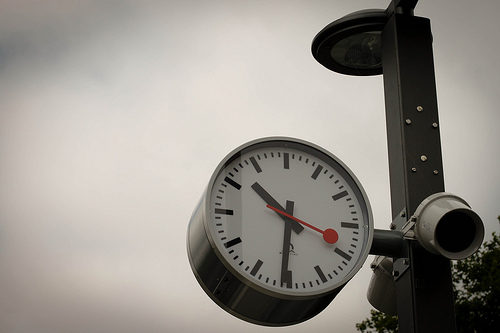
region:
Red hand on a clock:
[263, 198, 348, 246]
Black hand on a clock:
[245, 179, 305, 291]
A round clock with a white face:
[171, 136, 380, 332]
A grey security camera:
[398, 182, 498, 262]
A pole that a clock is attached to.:
[308, 7, 490, 332]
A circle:
[194, 130, 376, 312]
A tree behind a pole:
[329, 206, 498, 332]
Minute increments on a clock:
[253, 148, 288, 165]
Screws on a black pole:
[386, 91, 446, 188]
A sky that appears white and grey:
[3, 7, 185, 274]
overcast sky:
[14, 8, 174, 315]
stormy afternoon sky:
[7, 11, 176, 320]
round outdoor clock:
[182, 125, 384, 332]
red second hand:
[252, 202, 346, 247]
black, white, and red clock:
[166, 137, 388, 332]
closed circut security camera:
[389, 182, 494, 276]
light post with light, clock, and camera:
[118, 5, 495, 329]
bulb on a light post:
[290, 7, 454, 96]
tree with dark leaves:
[457, 254, 499, 325]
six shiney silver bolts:
[400, 92, 443, 186]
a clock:
[196, 90, 302, 325]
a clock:
[247, 132, 324, 309]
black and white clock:
[176, 128, 371, 323]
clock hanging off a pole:
[182, 134, 497, 321]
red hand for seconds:
[265, 200, 341, 247]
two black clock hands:
[251, 172, 302, 284]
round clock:
[170, 138, 373, 329]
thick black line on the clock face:
[247, 252, 267, 280]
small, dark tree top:
[448, 237, 498, 332]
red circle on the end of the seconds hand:
[317, 224, 342, 248]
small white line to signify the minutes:
[293, 150, 296, 160]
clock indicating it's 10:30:
[181, 118, 383, 312]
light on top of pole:
[283, 6, 406, 76]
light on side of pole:
[416, 177, 491, 279]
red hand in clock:
[265, 203, 347, 245]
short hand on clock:
[240, 183, 282, 215]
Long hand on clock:
[276, 195, 296, 287]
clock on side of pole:
[173, 84, 381, 330]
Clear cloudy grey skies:
[71, 85, 176, 146]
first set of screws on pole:
[398, 97, 445, 139]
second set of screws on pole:
[410, 148, 441, 188]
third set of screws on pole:
[377, 200, 416, 297]